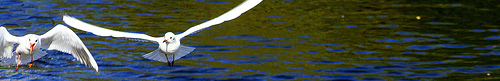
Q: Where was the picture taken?
A: The ocean.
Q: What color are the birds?
A: White.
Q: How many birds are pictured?
A: Two.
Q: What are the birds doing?
A: Flying.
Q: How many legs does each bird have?
A: Two.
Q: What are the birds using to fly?
A: Wings.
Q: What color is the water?
A: Blue.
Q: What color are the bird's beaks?
A: Orange.